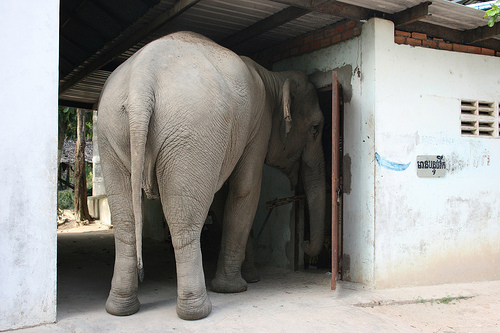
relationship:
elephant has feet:
[97, 31, 324, 320] [95, 268, 259, 321]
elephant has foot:
[97, 31, 324, 320] [175, 304, 211, 321]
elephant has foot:
[97, 31, 324, 320] [103, 299, 142, 315]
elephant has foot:
[97, 31, 324, 320] [207, 279, 248, 295]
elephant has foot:
[97, 31, 324, 320] [240, 270, 260, 283]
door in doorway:
[330, 77, 340, 291] [298, 84, 341, 278]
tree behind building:
[74, 108, 93, 223] [59, 2, 499, 286]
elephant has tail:
[97, 31, 324, 320] [127, 90, 156, 284]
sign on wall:
[414, 155, 447, 179] [373, 19, 497, 288]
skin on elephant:
[97, 30, 328, 320] [97, 31, 324, 320]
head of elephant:
[276, 70, 328, 258] [97, 31, 324, 320]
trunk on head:
[300, 149, 328, 256] [276, 70, 328, 258]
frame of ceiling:
[218, 0, 427, 47] [60, 0, 490, 113]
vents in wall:
[459, 99, 499, 140] [373, 19, 497, 288]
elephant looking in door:
[97, 31, 324, 320] [330, 77, 340, 291]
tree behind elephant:
[74, 108, 93, 223] [97, 31, 324, 320]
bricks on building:
[395, 29, 498, 58] [59, 2, 499, 286]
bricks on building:
[231, 19, 361, 61] [59, 2, 499, 286]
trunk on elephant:
[300, 149, 328, 256] [97, 31, 324, 320]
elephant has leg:
[97, 31, 324, 320] [156, 157, 219, 321]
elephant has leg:
[97, 31, 324, 320] [101, 158, 144, 315]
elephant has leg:
[97, 31, 324, 320] [213, 143, 248, 294]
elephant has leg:
[97, 31, 324, 320] [244, 232, 261, 281]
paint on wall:
[374, 151, 411, 172] [373, 19, 497, 288]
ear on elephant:
[283, 78, 298, 137] [97, 31, 324, 320]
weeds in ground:
[55, 190, 77, 208] [57, 205, 107, 233]